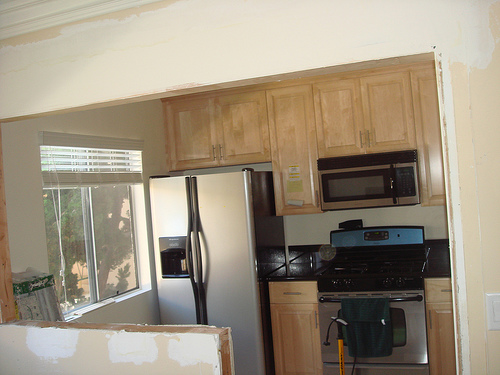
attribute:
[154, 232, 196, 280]
ice maker — black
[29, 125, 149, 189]
blinds — white, drawn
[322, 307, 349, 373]
pump — yellow, black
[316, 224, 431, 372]
stove — black, silver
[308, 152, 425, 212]
microwave — black, grey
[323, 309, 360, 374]
pump — yellow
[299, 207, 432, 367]
oven — silver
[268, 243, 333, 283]
countertops — black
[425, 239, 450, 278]
countertops — black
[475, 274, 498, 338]
light switch — white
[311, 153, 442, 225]
microwave — black, silver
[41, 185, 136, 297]
window — square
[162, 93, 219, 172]
cabinets — brown, wooden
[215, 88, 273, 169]
cabinets — brown, wooden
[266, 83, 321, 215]
cabinets — brown, wooden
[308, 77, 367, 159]
cabinets — brown, wooden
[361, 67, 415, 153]
cabinets — brown, wooden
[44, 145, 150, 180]
blinds — white, mini, pulled up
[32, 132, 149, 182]
shades — white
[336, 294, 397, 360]
towel — forest green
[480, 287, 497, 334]
switch — white 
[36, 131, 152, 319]
window — sliding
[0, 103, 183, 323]
wall — white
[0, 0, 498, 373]
wall — white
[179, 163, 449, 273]
wall — white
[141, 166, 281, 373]
refrigerator — black, silver, double-doored, stainless steel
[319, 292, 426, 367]
oven — silver, black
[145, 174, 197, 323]
door — silver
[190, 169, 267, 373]
door — silver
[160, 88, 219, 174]
cabinet — wooden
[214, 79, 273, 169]
cabinet — wooden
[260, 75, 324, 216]
cabinet — wooden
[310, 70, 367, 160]
cabinet — wooden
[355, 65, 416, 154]
cabinet — wooden